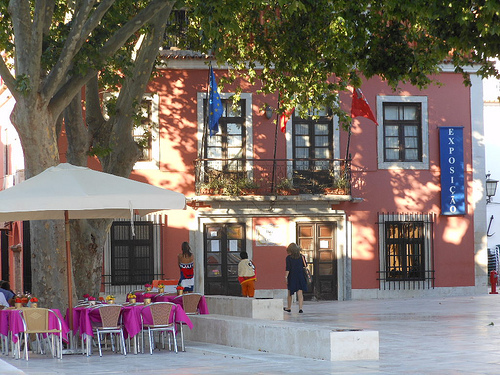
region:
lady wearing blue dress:
[278, 239, 318, 298]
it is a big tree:
[6, 2, 468, 152]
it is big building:
[164, 57, 495, 284]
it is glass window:
[377, 92, 430, 171]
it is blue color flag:
[205, 60, 226, 145]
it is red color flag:
[349, 84, 376, 133]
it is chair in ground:
[78, 298, 185, 359]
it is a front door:
[302, 220, 346, 307]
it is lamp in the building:
[485, 172, 497, 207]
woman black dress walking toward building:
[276, 239, 318, 320]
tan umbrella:
[6, 158, 194, 236]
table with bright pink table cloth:
[70, 298, 137, 353]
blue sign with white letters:
[427, 115, 478, 232]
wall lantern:
[479, 167, 499, 206]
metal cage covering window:
[372, 207, 441, 293]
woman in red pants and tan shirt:
[230, 245, 265, 302]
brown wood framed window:
[374, 90, 431, 172]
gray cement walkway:
[385, 303, 461, 361]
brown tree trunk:
[12, 91, 78, 302]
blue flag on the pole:
[201, 61, 221, 156]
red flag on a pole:
[321, 73, 378, 165]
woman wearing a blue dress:
[280, 253, 312, 298]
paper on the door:
[206, 231, 222, 257]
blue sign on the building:
[436, 121, 476, 228]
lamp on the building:
[482, 170, 499, 197]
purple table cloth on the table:
[79, 301, 145, 332]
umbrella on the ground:
[12, 160, 193, 352]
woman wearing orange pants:
[238, 273, 260, 303]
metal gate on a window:
[374, 203, 438, 293]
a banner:
[433, 124, 468, 219]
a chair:
[25, 309, 65, 356]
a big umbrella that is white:
[6, 163, 167, 208]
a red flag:
[336, 87, 386, 122]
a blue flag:
[206, 78, 221, 124]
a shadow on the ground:
[370, 300, 466, 326]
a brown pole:
[58, 223, 81, 300]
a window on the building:
[295, 128, 327, 162]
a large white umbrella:
[25, 163, 162, 240]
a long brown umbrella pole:
[38, 215, 82, 340]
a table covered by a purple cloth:
[4, 311, 74, 352]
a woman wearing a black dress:
[274, 243, 312, 324]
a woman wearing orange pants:
[237, 255, 259, 299]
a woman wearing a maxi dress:
[164, 242, 209, 294]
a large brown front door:
[281, 215, 351, 302]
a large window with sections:
[292, 99, 340, 199]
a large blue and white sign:
[442, 126, 477, 246]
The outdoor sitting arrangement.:
[1, 279, 205, 360]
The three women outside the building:
[179, 241, 312, 316]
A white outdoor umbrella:
[0, 164, 189, 374]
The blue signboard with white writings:
[439, 126, 471, 213]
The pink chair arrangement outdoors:
[1, 288, 211, 362]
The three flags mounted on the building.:
[195, 73, 377, 196]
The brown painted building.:
[0, 0, 497, 301]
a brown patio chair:
[138, 302, 180, 355]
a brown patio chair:
[87, 302, 129, 355]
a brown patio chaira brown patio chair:
[171, 291, 202, 314]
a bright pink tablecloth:
[78, 304, 137, 337]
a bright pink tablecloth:
[139, 301, 193, 330]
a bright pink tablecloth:
[0, 308, 68, 338]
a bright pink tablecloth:
[155, 294, 207, 314]